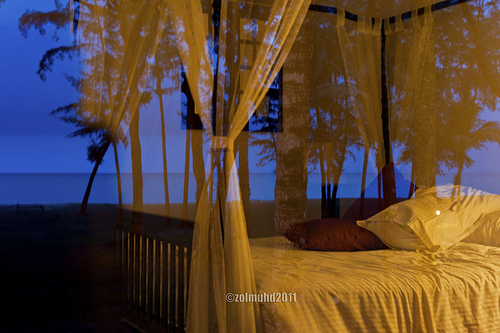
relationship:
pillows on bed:
[283, 160, 500, 252] [75, 0, 498, 332]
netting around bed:
[67, 16, 482, 173] [118, 201, 498, 331]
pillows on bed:
[283, 180, 498, 260] [118, 201, 498, 331]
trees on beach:
[41, 56, 366, 230] [11, 190, 424, 226]